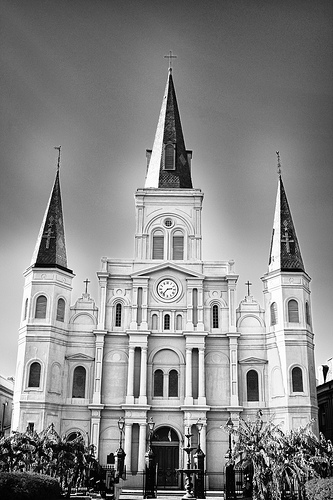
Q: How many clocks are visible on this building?
A: One.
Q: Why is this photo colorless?
A: A black and white filter.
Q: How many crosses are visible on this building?
A: Two.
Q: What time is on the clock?
A: 2:35.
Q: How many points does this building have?
A: Three.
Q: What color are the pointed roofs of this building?
A: Black.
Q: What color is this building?
A: White.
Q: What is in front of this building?
A: Vegetation.